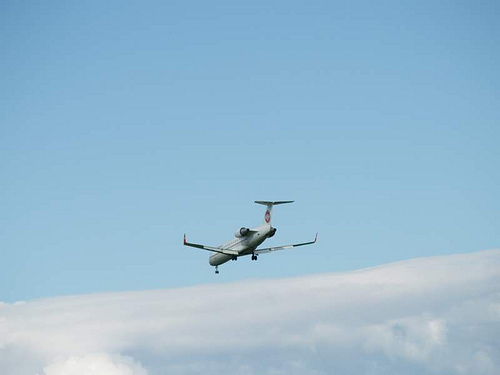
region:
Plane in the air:
[175, 192, 332, 278]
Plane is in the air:
[177, 192, 327, 277]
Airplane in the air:
[173, 192, 320, 275]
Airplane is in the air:
[175, 192, 327, 277]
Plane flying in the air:
[175, 190, 324, 277]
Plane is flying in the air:
[171, 196, 332, 276]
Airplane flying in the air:
[172, 189, 327, 280]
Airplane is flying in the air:
[169, 192, 335, 285]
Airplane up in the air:
[179, 192, 324, 274]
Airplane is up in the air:
[171, 190, 324, 275]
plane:
[148, 185, 323, 276]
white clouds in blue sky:
[52, 31, 126, 89]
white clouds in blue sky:
[380, 172, 404, 197]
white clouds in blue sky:
[414, 266, 441, 330]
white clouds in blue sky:
[408, 218, 456, 299]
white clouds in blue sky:
[314, 316, 369, 357]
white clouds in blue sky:
[255, 325, 326, 373]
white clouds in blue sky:
[138, 311, 190, 349]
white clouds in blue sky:
[42, 319, 117, 354]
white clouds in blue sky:
[331, 329, 411, 373]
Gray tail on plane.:
[251, 194, 302, 209]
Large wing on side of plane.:
[273, 235, 335, 262]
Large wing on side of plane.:
[177, 229, 227, 261]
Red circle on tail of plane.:
[259, 208, 290, 224]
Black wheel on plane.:
[211, 268, 226, 277]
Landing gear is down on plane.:
[225, 253, 254, 290]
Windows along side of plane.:
[220, 234, 250, 242]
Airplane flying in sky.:
[183, 203, 313, 298]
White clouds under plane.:
[71, 304, 247, 351]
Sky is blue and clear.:
[63, 141, 215, 148]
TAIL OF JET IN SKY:
[246, 194, 307, 212]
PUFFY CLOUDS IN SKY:
[42, 310, 105, 358]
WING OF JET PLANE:
[261, 231, 327, 251]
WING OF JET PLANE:
[175, 231, 236, 251]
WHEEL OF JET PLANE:
[213, 265, 223, 275]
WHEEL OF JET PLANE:
[232, 253, 240, 263]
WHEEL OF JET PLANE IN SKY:
[248, 250, 262, 264]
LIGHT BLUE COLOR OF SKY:
[99, 108, 218, 147]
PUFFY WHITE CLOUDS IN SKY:
[303, 284, 367, 316]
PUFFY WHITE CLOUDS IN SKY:
[347, 341, 457, 371]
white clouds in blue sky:
[332, 253, 364, 288]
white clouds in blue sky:
[318, 351, 352, 368]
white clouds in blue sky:
[248, 329, 303, 360]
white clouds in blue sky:
[162, 312, 254, 372]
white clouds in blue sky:
[61, 303, 133, 350]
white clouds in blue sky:
[137, 321, 207, 365]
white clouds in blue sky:
[24, 311, 99, 358]